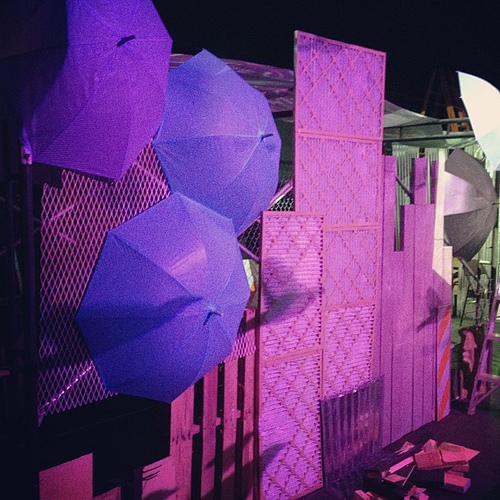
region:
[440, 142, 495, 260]
the umbrella is gray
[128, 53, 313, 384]
the umbrellas are blue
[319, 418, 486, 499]
blocks on the ground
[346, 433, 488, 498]
a pile of blocks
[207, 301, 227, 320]
rod sticking out of the top of the umbrella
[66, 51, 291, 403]
two open blue umbrellas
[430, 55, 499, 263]
white umbrella by a black one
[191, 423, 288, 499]
shadows on the wall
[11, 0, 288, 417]
three umbrellas hanging on the wall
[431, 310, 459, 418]
orange and gray stripes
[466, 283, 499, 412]
part of a ladder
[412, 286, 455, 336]
shadow in the shape of a bird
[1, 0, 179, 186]
a purple hung umbrella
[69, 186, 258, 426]
a purple hung umbrella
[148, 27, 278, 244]
a purple hung umbrella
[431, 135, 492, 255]
a grey hung umbrella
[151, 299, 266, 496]
a purple wooden pallet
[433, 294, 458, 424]
an orange and purple contruction sign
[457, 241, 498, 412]
a purple step ladder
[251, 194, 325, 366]
an air filter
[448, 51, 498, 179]
a white hung umbrella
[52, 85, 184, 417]
a metal grate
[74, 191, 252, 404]
Purple umbrella near purple umbrella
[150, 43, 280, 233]
Purple umbrella near purple umbrella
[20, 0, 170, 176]
Purple umbrella near purple umbrella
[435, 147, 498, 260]
Gray umbrella near white umbrella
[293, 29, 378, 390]
Purple panel near purple panel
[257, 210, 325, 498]
Purple panel near purple panel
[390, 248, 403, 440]
Purple plank near purple plank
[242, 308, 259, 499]
Purple plank near umbrella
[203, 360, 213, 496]
Purple plank near purple plank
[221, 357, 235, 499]
Purple plank near purple plank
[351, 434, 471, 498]
Pile of books on the ground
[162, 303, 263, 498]
Four post wood fence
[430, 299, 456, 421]
Rectangular sign with diagonal orange lines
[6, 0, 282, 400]
Three purple umbrellas hangings from a grate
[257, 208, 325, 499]
Two air filters stacked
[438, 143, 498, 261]
Gray umbrella on a wall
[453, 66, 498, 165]
White umbrella on a pole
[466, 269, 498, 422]
Metal ladder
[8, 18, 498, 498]
Purple tinted lighting on a background scene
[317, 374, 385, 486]
Shiny material against the wall